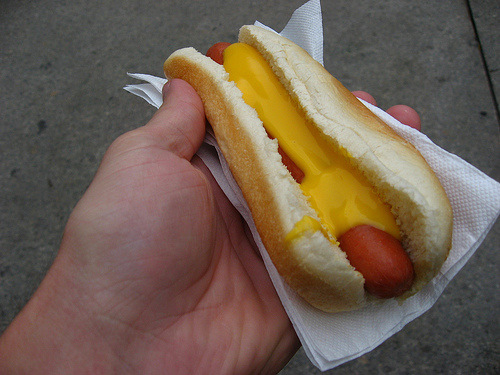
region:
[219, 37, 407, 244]
Mustard on a hot dog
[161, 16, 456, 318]
A hot dog in a bun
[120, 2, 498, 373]
Hot dog on a white napkin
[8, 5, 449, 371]
A hot dog in a hand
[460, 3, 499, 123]
A line on the ground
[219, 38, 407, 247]
The mustard is yellow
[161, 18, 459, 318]
The hot dog bun is light brown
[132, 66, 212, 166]
A thumb on a hand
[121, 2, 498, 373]
A napkin is rectangular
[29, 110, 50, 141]
A spot on the ground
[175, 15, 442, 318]
A hotdog in a hand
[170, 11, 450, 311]
A weiner on a bun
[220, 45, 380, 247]
Mustard on the hotdog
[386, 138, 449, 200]
A hotdog bun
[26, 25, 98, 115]
A grey counter in background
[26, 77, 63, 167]
Dark grey spots on counter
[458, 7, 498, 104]
A dark streak or line on counter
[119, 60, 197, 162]
A persons thumb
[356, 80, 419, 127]
Fingertips under hotdog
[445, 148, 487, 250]
A white napkin under hand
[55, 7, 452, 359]
hand holding a hot dog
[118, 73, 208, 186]
the thumb of a hand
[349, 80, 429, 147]
fingers behind a napkin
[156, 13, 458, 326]
a bun with a hot dog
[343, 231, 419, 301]
the tip of the hot dog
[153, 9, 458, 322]
mustard on the hot dog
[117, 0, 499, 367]
a napkin over a hand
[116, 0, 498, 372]
a hot dog over a napkin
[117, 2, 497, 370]
a white napkin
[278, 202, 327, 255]
mustard over the bun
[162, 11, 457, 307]
A hot dog on a bun covered in cheese sauce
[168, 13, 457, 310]
A hot dog on a bun smothered in cheese sauce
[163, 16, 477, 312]
A hot dog on a bun covered in melted cheese sauce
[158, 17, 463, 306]
A hotdog on a bun with cheddar cheese sauce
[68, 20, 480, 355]
A hand holding a hotdog on a bun with cheese sauce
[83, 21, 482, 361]
A hand holding a hotdog on a bun with melted cheese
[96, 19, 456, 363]
A hand holding a hotdog on a bun smothered in cheddar cheese sauce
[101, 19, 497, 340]
A hand holding a hotdog on a bun smothered in melted cheese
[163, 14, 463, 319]
A hotdog with cheddar cheese sauce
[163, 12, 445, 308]
A hot dog smothered in nacho cheese sauce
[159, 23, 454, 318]
A hotdog on a bun.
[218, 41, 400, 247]
Lots of yellow mustard.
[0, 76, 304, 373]
Part of a human hand.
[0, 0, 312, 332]
An area of gray pavement.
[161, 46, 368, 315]
Half of a hotdog bun.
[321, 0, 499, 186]
A gray paved sidewalk.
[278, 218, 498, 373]
An area of gray cement.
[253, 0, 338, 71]
Part of a napkin.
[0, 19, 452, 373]
A hand holding a hotdog.